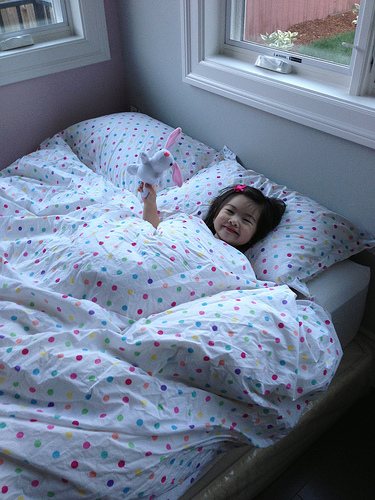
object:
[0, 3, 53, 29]
rail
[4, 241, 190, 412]
cover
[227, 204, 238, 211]
eyebrow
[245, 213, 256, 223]
eyebrow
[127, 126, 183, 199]
bunny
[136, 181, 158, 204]
right hand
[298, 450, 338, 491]
floor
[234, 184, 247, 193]
pink bow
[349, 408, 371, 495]
floor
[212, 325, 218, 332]
polka dots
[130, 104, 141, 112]
outlet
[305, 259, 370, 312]
sheet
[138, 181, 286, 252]
girl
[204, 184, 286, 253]
hair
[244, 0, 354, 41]
fence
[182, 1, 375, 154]
window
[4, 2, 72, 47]
window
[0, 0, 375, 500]
room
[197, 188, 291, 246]
teddy bear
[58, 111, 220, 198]
pillow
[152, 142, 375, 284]
pollow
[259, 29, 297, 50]
plants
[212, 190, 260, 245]
smile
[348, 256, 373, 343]
corner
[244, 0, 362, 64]
outside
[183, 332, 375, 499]
mattress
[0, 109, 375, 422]
bed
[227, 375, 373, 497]
foundation